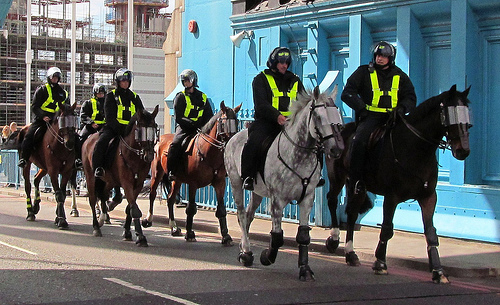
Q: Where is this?
A: This is at the road.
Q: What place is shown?
A: It is a road.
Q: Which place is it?
A: It is a road.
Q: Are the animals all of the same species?
A: Yes, all the animals are horses.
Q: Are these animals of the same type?
A: Yes, all the animals are horses.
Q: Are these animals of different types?
A: No, all the animals are horses.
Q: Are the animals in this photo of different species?
A: No, all the animals are horses.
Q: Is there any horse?
A: Yes, there is a horse.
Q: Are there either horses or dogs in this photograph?
A: Yes, there is a horse.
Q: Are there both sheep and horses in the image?
A: No, there is a horse but no sheep.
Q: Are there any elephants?
A: No, there are no elephants.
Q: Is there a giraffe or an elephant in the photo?
A: No, there are no elephants or giraffes.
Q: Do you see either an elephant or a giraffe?
A: No, there are no elephants or giraffes.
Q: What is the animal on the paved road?
A: The animal is a horse.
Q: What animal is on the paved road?
A: The animal is a horse.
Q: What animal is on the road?
A: The animal is a horse.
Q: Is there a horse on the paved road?
A: Yes, there is a horse on the road.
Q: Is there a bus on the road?
A: No, there is a horse on the road.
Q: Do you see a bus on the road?
A: No, there is a horse on the road.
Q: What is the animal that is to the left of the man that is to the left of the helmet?
A: The animal is a horse.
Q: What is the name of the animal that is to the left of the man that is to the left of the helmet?
A: The animal is a horse.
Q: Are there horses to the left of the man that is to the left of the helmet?
A: Yes, there is a horse to the left of the man.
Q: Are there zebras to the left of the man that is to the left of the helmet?
A: No, there is a horse to the left of the man.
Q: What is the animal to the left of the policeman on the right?
A: The animal is a horse.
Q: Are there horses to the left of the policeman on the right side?
A: Yes, there is a horse to the left of the policeman.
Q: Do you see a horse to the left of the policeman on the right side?
A: Yes, there is a horse to the left of the policeman.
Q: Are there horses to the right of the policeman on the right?
A: No, the horse is to the left of the police officer.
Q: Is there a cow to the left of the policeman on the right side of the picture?
A: No, there is a horse to the left of the policeman.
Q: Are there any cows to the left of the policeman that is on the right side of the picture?
A: No, there is a horse to the left of the policeman.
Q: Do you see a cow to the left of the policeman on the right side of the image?
A: No, there is a horse to the left of the policeman.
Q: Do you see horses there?
A: Yes, there is a horse.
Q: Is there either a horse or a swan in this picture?
A: Yes, there is a horse.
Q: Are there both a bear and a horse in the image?
A: No, there is a horse but no bears.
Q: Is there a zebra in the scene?
A: No, there are no zebras.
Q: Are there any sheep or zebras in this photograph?
A: No, there are no zebras or sheep.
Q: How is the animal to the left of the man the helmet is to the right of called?
A: The animal is a horse.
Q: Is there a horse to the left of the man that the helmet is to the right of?
A: Yes, there is a horse to the left of the man.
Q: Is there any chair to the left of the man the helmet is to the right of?
A: No, there is a horse to the left of the man.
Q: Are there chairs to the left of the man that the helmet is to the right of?
A: No, there is a horse to the left of the man.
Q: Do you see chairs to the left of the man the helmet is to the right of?
A: No, there is a horse to the left of the man.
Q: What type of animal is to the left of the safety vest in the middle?
A: The animal is a horse.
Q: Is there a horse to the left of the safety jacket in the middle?
A: Yes, there is a horse to the left of the safety vest.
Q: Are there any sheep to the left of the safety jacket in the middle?
A: No, there is a horse to the left of the safety vest.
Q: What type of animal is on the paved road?
A: The animal is a horse.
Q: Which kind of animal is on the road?
A: The animal is a horse.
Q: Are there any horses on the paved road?
A: Yes, there is a horse on the road.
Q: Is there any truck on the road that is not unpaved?
A: No, there is a horse on the road.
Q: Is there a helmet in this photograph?
A: Yes, there is a helmet.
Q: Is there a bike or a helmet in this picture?
A: Yes, there is a helmet.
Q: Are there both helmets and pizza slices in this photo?
A: No, there is a helmet but no pizza slices.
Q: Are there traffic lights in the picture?
A: No, there are no traffic lights.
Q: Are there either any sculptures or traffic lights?
A: No, there are no traffic lights or sculptures.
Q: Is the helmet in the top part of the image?
A: Yes, the helmet is in the top of the image.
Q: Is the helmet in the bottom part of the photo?
A: No, the helmet is in the top of the image.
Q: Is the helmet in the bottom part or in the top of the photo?
A: The helmet is in the top of the image.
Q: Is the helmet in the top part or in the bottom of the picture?
A: The helmet is in the top of the image.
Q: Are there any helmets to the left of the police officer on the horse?
A: Yes, there is a helmet to the left of the police officer.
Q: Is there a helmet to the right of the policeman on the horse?
A: No, the helmet is to the left of the policeman.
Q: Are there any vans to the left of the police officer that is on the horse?
A: No, there is a helmet to the left of the policeman.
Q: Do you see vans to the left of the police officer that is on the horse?
A: No, there is a helmet to the left of the policeman.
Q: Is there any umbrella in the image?
A: No, there are no umbrellas.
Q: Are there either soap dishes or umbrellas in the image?
A: No, there are no umbrellas or soap dishes.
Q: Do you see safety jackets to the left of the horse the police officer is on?
A: Yes, there is a safety jacket to the left of the horse.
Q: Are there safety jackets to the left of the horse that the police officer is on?
A: Yes, there is a safety jacket to the left of the horse.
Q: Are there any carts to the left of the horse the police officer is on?
A: No, there is a safety jacket to the left of the horse.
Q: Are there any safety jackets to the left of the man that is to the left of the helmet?
A: Yes, there is a safety jacket to the left of the man.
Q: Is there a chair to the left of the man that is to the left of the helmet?
A: No, there is a safety jacket to the left of the man.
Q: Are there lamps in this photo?
A: No, there are no lamps.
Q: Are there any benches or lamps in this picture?
A: No, there are no lamps or benches.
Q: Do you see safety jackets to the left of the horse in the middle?
A: Yes, there is a safety jacket to the left of the horse.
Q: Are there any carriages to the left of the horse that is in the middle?
A: No, there is a safety jacket to the left of the horse.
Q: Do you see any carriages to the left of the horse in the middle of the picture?
A: No, there is a safety jacket to the left of the horse.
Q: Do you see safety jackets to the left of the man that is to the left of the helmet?
A: Yes, there is a safety jacket to the left of the man.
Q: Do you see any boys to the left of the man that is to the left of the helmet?
A: No, there is a safety jacket to the left of the man.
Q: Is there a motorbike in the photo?
A: No, there are no motorcycles.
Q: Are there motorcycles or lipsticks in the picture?
A: No, there are no motorcycles or lipsticks.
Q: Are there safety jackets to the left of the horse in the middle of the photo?
A: Yes, there is a safety jacket to the left of the horse.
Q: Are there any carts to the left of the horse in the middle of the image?
A: No, there is a safety jacket to the left of the horse.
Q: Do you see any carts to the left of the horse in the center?
A: No, there is a safety jacket to the left of the horse.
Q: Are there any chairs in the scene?
A: No, there are no chairs.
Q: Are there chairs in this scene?
A: No, there are no chairs.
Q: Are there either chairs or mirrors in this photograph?
A: No, there are no chairs or mirrors.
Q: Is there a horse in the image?
A: Yes, there is a horse.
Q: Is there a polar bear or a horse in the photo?
A: Yes, there is a horse.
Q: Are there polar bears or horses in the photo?
A: Yes, there is a horse.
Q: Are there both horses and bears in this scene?
A: No, there is a horse but no bears.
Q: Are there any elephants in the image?
A: No, there are no elephants.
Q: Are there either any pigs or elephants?
A: No, there are no elephants or pigs.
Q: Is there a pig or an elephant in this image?
A: No, there are no elephants or pigs.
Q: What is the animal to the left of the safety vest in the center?
A: The animal is a horse.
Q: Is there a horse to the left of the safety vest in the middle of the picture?
A: Yes, there is a horse to the left of the safety jacket.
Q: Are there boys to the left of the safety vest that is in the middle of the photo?
A: No, there is a horse to the left of the safety vest.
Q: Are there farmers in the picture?
A: No, there are no farmers.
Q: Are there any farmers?
A: No, there are no farmers.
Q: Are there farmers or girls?
A: No, there are no farmers or girls.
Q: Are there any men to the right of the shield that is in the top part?
A: Yes, there is a man to the right of the shield.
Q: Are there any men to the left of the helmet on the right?
A: Yes, there is a man to the left of the helmet.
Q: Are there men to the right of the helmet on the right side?
A: No, the man is to the left of the helmet.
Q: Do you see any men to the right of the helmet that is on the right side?
A: No, the man is to the left of the helmet.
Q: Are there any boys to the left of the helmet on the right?
A: No, there is a man to the left of the helmet.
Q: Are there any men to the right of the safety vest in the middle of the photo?
A: Yes, there is a man to the right of the safety vest.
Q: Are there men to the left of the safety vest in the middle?
A: No, the man is to the right of the safety jacket.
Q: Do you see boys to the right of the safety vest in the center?
A: No, there is a man to the right of the safety vest.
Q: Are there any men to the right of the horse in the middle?
A: Yes, there is a man to the right of the horse.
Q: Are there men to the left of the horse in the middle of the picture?
A: No, the man is to the right of the horse.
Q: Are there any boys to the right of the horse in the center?
A: No, there is a man to the right of the horse.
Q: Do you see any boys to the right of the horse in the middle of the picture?
A: No, there is a man to the right of the horse.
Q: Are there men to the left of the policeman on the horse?
A: Yes, there is a man to the left of the police officer.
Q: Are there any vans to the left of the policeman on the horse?
A: No, there is a man to the left of the policeman.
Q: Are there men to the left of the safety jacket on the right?
A: Yes, there is a man to the left of the safety jacket.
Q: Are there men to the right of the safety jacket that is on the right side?
A: No, the man is to the left of the safety jacket.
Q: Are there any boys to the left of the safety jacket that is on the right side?
A: No, there is a man to the left of the safety vest.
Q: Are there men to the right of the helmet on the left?
A: Yes, there is a man to the right of the helmet.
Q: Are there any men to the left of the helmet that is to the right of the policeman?
A: No, the man is to the right of the helmet.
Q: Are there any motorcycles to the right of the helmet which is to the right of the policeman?
A: No, there is a man to the right of the helmet.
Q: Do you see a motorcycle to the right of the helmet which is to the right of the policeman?
A: No, there is a man to the right of the helmet.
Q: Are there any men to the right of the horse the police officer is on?
A: No, the man is to the left of the horse.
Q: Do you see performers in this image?
A: No, there are no performers.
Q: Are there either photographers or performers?
A: No, there are no performers or photographers.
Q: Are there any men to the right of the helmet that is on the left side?
A: Yes, there is a man to the right of the helmet.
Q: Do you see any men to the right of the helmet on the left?
A: Yes, there is a man to the right of the helmet.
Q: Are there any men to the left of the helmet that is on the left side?
A: No, the man is to the right of the helmet.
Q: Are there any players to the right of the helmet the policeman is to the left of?
A: No, there is a man to the right of the helmet.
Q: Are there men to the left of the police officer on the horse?
A: Yes, there is a man to the left of the policeman.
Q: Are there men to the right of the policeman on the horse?
A: No, the man is to the left of the policeman.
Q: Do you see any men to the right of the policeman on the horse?
A: No, the man is to the left of the policeman.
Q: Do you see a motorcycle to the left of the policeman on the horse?
A: No, there is a man to the left of the policeman.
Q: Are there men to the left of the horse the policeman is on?
A: Yes, there is a man to the left of the horse.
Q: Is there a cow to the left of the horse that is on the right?
A: No, there is a man to the left of the horse.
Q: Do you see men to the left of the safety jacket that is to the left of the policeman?
A: Yes, there is a man to the left of the safety jacket.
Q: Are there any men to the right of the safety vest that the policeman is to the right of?
A: No, the man is to the left of the safety jacket.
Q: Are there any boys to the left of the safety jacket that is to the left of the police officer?
A: No, there is a man to the left of the safety vest.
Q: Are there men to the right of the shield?
A: Yes, there is a man to the right of the shield.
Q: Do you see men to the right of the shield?
A: Yes, there is a man to the right of the shield.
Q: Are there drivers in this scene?
A: No, there are no drivers.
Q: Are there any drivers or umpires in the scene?
A: No, there are no drivers or umpires.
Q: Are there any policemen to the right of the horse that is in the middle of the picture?
A: Yes, there is a policeman to the right of the horse.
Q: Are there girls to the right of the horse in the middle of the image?
A: No, there is a policeman to the right of the horse.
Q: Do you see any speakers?
A: Yes, there is a speaker.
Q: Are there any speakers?
A: Yes, there is a speaker.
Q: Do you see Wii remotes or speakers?
A: Yes, there is a speaker.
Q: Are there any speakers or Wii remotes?
A: Yes, there is a speaker.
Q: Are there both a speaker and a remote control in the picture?
A: No, there is a speaker but no remote controls.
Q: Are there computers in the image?
A: No, there are no computers.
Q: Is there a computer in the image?
A: No, there are no computers.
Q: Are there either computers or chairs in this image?
A: No, there are no computers or chairs.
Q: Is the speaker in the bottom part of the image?
A: No, the speaker is in the top of the image.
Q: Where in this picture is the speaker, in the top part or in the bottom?
A: The speaker is in the top of the image.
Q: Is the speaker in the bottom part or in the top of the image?
A: The speaker is in the top of the image.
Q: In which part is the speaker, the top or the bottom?
A: The speaker is in the top of the image.